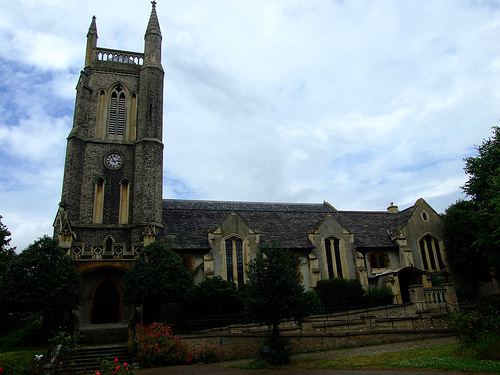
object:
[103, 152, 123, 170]
clock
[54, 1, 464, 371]
building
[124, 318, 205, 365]
flowers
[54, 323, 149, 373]
stairs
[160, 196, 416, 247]
roof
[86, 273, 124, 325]
doorway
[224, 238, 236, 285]
window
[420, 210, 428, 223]
window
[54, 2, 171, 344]
tower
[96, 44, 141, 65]
small dome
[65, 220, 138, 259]
wall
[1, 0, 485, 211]
clouds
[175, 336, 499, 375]
grass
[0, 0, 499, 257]
sky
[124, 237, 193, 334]
tree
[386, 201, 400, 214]
chimney